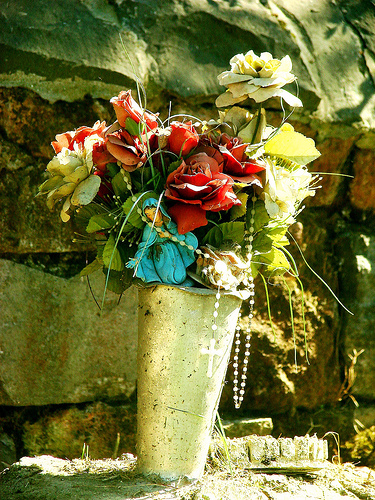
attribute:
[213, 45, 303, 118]
rose — yellow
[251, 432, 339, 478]
dirt — bunch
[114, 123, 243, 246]
flowers — colorful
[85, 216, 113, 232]
leaf —  Light green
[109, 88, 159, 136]
rose —  red ,  Closed up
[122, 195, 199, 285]
statue —   of woman,  in blue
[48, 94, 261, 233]
roses — red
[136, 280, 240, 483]
stone vase — light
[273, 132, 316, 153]
petals —  Light yellow,  flower's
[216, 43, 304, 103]
rose —  opened,  yellow 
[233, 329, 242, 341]
bead —  Silver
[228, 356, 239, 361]
bead —  Silver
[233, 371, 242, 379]
bead —  Silver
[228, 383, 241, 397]
bead —  Silver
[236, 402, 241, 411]
bead —  Silver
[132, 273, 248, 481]
vase —  metal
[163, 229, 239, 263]
beads — white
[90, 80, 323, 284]
flowers — bunch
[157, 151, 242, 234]
rose —  red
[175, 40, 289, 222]
roses — yellow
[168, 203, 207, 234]
petal —  Red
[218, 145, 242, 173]
petal —  Red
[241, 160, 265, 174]
petal —  Red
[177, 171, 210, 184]
petal —  Red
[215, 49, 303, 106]
rose — white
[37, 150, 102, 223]
flower —  multi-colored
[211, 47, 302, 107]
flower —  multi-colored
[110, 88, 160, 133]
flower —  multi-colored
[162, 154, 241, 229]
flower —  multi-colored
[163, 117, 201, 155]
flower —  multi-colored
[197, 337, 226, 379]
cross —  Silver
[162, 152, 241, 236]
rose —  opened,   red 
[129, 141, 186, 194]
hoops — grey, metal